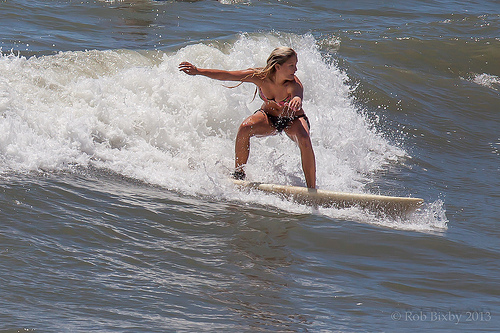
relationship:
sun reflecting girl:
[154, 20, 222, 71] [173, 36, 352, 207]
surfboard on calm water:
[171, 157, 453, 234] [2, 0, 500, 331]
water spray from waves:
[31, 17, 401, 210] [57, 34, 388, 168]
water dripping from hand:
[276, 99, 304, 163] [164, 28, 248, 136]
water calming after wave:
[118, 168, 494, 263] [52, 43, 329, 209]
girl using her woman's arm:
[173, 36, 352, 207] [171, 54, 266, 100]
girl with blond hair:
[189, 38, 398, 294] [217, 43, 300, 105]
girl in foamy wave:
[173, 36, 352, 207] [0, 27, 408, 212]